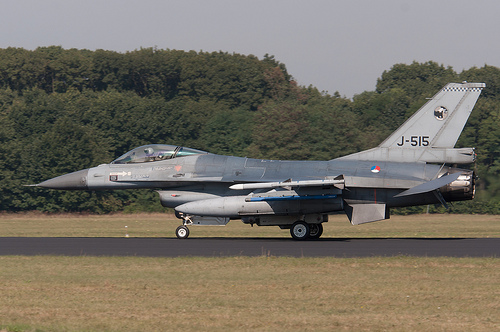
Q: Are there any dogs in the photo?
A: No, there are no dogs.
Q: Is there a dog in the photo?
A: No, there are no dogs.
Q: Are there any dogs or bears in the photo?
A: No, there are no dogs or bears.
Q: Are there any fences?
A: No, there are no fences.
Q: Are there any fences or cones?
A: No, there are no fences or cones.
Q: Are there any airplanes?
A: Yes, there is an airplane.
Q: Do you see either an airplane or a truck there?
A: Yes, there is an airplane.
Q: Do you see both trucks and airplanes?
A: No, there is an airplane but no trucks.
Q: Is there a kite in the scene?
A: No, there are no kites.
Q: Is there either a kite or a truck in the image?
A: No, there are no kites or trucks.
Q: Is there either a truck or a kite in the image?
A: No, there are no kites or trucks.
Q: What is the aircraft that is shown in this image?
A: The aircraft is an airplane.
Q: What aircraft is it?
A: The aircraft is an airplane.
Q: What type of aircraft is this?
A: That is an airplane.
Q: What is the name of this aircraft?
A: That is an airplane.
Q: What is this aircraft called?
A: That is an airplane.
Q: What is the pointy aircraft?
A: The aircraft is an airplane.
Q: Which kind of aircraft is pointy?
A: The aircraft is an airplane.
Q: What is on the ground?
A: The airplane is on the ground.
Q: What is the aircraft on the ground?
A: The aircraft is an airplane.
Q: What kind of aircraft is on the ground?
A: The aircraft is an airplane.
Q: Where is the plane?
A: The plane is on the ground.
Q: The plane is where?
A: The plane is on the ground.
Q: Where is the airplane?
A: The plane is on the ground.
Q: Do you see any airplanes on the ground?
A: Yes, there is an airplane on the ground.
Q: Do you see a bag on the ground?
A: No, there is an airplane on the ground.